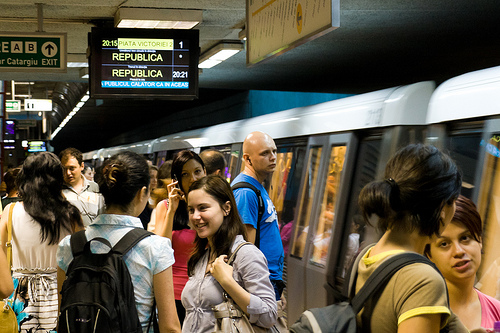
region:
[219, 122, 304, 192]
Shaved head on a man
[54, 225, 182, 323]
Black back pack on a woman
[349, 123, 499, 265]
Dark hair on a woman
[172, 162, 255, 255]
Smile on a woman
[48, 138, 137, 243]
Man with dark hair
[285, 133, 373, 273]
Window on a train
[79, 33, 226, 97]
Sign in a station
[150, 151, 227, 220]
Woman on a phone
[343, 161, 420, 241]
Ponytail in a woman's hair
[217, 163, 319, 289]
Blue shirt on a man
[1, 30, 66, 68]
green sign with white lettering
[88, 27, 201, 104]
black monitor showing schedule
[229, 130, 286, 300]
bald man wearing blue shirt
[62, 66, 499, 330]
white and grey subway car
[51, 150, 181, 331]
young girl wearing black backpack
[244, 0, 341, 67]
hanging sign with subway stops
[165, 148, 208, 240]
woman talking on cell phone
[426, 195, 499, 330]
young woman wearing pink shirt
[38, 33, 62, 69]
sign indicating exit direction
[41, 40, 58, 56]
white circle encasing a green arrow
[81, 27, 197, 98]
a screen showing the time for trains above the people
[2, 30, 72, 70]
a sign showing the way to the exit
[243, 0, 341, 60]
the subway route on the sign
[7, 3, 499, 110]
the ceiling above everything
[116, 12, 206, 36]
a light by the screen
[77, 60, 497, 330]
the subway train next to the people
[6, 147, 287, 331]
a crowd of people waiting for the subway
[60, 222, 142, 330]
the black backpack the woman is wearing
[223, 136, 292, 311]
the man in the blue shirt waiting for the train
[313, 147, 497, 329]
two women talking to each other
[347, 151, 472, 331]
a woman wearing a yellow shirt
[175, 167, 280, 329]
a woman with a smile.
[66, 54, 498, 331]
a train waiting in a train station.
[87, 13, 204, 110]
a monitor with a train schedule.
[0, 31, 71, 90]
a sign suspended from a ceiling.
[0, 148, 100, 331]
a woman in a colorful outfit.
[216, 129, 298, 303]
a man in a blue shirt.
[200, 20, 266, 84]
a light suspended from a ceiling.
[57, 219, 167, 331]
a black back pack.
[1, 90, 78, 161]
over head displays.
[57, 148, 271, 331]
Two friends talking to each other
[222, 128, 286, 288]
Man wearing a blue shirt with backpack.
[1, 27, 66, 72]
Exit sign displayed above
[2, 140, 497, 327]
Crowd of people waiting to board.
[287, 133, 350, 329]
A door to the train car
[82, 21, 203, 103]
Electronic message board above the tracks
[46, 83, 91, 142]
Fluorescent overhead lights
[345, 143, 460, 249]
Woman with a ponytail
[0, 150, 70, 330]
Woman in a white and gray dress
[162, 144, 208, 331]
Woman with her fingers crossed.